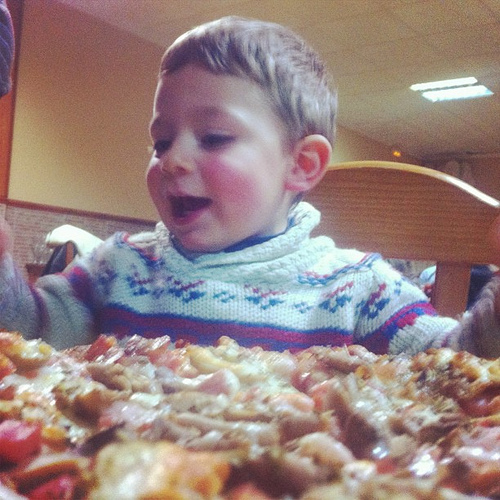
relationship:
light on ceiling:
[434, 73, 483, 113] [364, 2, 447, 40]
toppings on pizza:
[280, 385, 416, 471] [102, 362, 290, 441]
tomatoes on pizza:
[75, 335, 122, 358] [102, 362, 290, 441]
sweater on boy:
[123, 259, 333, 338] [72, 16, 409, 334]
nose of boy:
[161, 157, 195, 177] [72, 16, 409, 334]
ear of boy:
[281, 126, 336, 187] [72, 16, 409, 334]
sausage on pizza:
[249, 447, 300, 489] [102, 362, 290, 441]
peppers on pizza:
[55, 376, 128, 424] [102, 362, 290, 441]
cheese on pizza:
[121, 384, 229, 452] [102, 362, 290, 441]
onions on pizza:
[216, 371, 353, 473] [102, 362, 290, 441]